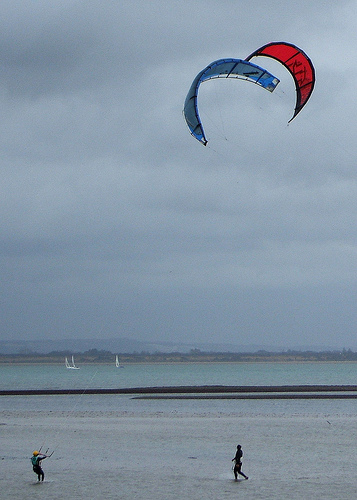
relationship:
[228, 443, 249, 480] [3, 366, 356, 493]
man in water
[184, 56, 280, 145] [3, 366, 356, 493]
kite flying over water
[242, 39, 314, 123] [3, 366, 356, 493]
kite flying over water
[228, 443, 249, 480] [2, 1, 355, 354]
man watching sky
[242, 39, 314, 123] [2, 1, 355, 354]
kite in sky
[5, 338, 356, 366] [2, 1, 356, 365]
moutains in horizon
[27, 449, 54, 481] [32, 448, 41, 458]
man has helmet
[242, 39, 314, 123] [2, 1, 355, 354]
kite flying in sky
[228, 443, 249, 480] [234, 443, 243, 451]
man has hair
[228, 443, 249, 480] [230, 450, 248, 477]
man wearing dark clothing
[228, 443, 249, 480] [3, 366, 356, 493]
man walking in water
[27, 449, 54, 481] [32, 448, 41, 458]
man wearing helmet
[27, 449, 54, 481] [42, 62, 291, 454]
man holding wires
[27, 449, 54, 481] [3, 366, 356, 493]
man standing in water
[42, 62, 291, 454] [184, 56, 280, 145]
wires are connected to kite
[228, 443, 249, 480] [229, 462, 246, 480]
man wearing dark pants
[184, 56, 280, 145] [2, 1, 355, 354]
kite in sky